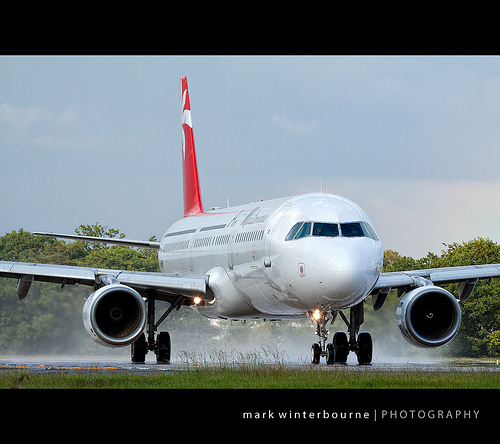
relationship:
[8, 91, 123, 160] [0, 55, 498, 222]
cloud in clouds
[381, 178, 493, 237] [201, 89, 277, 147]
clouds in sky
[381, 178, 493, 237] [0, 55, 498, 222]
clouds in clouds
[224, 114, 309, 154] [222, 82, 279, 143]
clouds in sky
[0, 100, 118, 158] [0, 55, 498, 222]
cloud in clouds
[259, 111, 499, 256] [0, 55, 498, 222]
clouds in clouds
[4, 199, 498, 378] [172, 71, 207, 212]
plane has tail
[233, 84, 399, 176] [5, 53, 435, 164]
clouds in sky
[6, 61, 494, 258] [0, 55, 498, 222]
clouds in clouds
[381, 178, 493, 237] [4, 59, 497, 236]
clouds in sky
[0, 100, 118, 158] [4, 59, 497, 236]
cloud in sky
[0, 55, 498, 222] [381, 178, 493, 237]
clouds has clouds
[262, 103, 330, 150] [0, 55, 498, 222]
clouds in clouds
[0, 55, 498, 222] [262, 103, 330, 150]
clouds has clouds